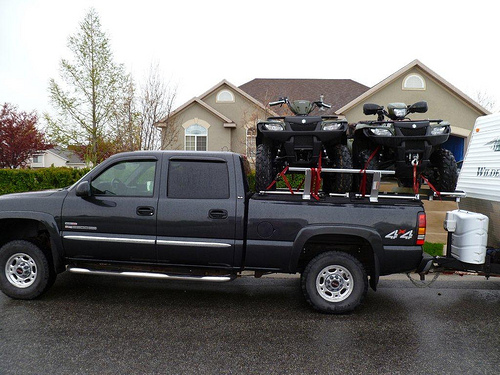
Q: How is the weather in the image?
A: It is cloudy.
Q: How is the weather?
A: It is cloudy.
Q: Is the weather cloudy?
A: Yes, it is cloudy.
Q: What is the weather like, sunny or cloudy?
A: It is cloudy.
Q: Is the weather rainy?
A: No, it is cloudy.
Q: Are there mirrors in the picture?
A: Yes, there is a mirror.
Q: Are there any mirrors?
A: Yes, there is a mirror.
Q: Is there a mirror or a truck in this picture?
A: Yes, there is a mirror.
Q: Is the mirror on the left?
A: Yes, the mirror is on the left of the image.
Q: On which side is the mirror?
A: The mirror is on the left of the image.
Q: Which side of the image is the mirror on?
A: The mirror is on the left of the image.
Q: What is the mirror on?
A: The mirror is on the door.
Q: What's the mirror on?
A: The mirror is on the door.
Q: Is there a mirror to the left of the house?
A: Yes, there is a mirror to the left of the house.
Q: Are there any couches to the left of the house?
A: No, there is a mirror to the left of the house.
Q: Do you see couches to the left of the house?
A: No, there is a mirror to the left of the house.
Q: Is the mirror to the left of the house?
A: Yes, the mirror is to the left of the house.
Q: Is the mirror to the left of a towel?
A: No, the mirror is to the left of the house.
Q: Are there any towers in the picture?
A: No, there are no towers.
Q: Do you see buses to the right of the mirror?
A: No, there is a house to the right of the mirror.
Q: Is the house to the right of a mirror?
A: Yes, the house is to the right of a mirror.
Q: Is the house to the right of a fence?
A: No, the house is to the right of a mirror.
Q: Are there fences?
A: No, there are no fences.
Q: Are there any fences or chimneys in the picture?
A: No, there are no fences or chimneys.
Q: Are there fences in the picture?
A: No, there are no fences.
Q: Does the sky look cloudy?
A: Yes, the sky is cloudy.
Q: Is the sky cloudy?
A: Yes, the sky is cloudy.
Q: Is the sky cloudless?
A: No, the sky is cloudy.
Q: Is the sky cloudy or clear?
A: The sky is cloudy.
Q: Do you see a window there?
A: Yes, there is a window.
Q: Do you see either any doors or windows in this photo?
A: Yes, there is a window.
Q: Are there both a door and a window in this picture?
A: Yes, there are both a window and a door.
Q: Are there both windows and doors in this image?
A: Yes, there are both a window and a door.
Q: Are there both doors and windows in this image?
A: Yes, there are both a window and a door.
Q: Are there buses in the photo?
A: No, there are no buses.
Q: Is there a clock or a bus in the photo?
A: No, there are no buses or clocks.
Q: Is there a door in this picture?
A: Yes, there is a door.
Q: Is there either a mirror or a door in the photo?
A: Yes, there is a door.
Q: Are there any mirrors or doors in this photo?
A: Yes, there is a door.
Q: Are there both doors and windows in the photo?
A: Yes, there are both a door and a window.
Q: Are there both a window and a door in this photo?
A: Yes, there are both a door and a window.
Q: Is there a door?
A: Yes, there is a door.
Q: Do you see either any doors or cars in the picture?
A: Yes, there is a door.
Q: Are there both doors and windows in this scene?
A: Yes, there are both a door and a window.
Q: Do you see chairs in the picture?
A: No, there are no chairs.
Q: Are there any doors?
A: Yes, there is a door.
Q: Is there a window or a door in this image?
A: Yes, there is a door.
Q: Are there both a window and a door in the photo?
A: Yes, there are both a door and a window.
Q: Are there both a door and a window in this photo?
A: Yes, there are both a door and a window.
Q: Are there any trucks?
A: Yes, there is a truck.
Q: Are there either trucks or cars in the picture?
A: Yes, there is a truck.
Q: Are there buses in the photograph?
A: No, there are no buses.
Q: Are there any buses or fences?
A: No, there are no buses or fences.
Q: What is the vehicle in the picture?
A: The vehicle is a truck.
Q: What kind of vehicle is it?
A: The vehicle is a truck.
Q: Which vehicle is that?
A: This is a truck.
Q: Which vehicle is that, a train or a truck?
A: This is a truck.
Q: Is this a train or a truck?
A: This is a truck.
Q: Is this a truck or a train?
A: This is a truck.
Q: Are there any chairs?
A: No, there are no chairs.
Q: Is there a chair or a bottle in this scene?
A: No, there are no chairs or bottles.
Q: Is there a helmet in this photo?
A: No, there are no helmets.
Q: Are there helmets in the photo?
A: No, there are no helmets.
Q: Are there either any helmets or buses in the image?
A: No, there are no helmets or buses.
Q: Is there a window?
A: Yes, there is a window.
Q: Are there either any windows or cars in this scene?
A: Yes, there is a window.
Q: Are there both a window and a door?
A: Yes, there are both a window and a door.